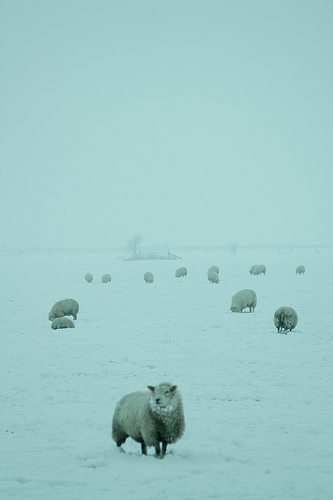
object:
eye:
[164, 390, 170, 397]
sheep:
[143, 266, 187, 283]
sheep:
[296, 265, 305, 275]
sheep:
[51, 316, 76, 329]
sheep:
[49, 298, 80, 322]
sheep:
[273, 306, 298, 333]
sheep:
[229, 288, 258, 313]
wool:
[58, 318, 68, 323]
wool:
[209, 267, 214, 276]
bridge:
[123, 248, 182, 263]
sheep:
[143, 271, 154, 283]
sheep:
[111, 380, 186, 460]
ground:
[0, 242, 333, 499]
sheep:
[207, 255, 267, 284]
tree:
[126, 230, 143, 257]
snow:
[0, 244, 333, 498]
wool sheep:
[174, 265, 257, 314]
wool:
[286, 308, 296, 326]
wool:
[233, 288, 253, 302]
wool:
[52, 298, 77, 314]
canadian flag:
[48, 298, 79, 330]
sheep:
[102, 272, 112, 284]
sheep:
[207, 271, 219, 284]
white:
[0, 228, 333, 500]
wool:
[112, 391, 150, 439]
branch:
[128, 249, 132, 256]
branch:
[137, 235, 140, 241]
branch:
[129, 241, 133, 248]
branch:
[132, 247, 135, 252]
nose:
[156, 397, 161, 401]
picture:
[1, 1, 333, 500]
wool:
[103, 274, 108, 279]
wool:
[146, 273, 153, 278]